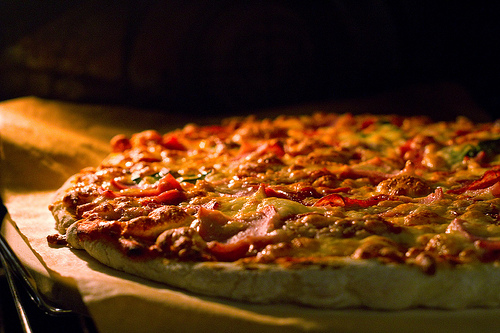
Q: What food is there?
A: Pizza.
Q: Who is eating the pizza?
A: No one.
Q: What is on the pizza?
A: Cheese.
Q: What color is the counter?
A: Brown.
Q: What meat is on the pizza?
A: Pepperoni.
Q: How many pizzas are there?
A: One.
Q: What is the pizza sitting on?
A: Paper.